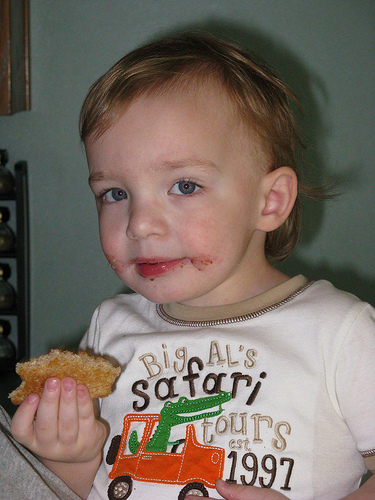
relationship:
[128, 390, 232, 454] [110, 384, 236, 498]
alligator driving truck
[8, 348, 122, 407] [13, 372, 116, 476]
bread in boy's hand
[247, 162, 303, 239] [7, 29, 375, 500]
ear of child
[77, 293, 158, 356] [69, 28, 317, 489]
shoulder of child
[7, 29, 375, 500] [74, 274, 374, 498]
child wearing shirt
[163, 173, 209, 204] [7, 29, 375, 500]
eye of child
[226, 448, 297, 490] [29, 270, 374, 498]
date on shirt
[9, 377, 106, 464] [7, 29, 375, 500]
boy's hand of child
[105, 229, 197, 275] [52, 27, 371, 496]
mouth of child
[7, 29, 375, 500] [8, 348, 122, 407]
child holding bread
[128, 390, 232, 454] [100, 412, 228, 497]
alligator driving truck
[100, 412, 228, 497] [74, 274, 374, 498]
truck on shirt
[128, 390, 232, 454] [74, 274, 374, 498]
alligator on shirt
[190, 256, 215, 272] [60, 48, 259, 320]
food on face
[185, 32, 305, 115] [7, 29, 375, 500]
cowlick of child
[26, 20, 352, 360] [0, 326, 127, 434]
child eating jelly bread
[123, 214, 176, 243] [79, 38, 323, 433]
nose of child